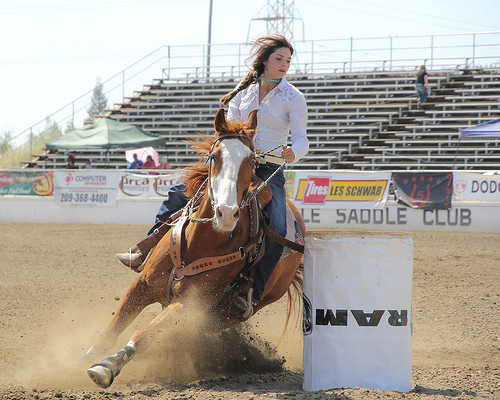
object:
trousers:
[141, 155, 290, 297]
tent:
[450, 115, 498, 171]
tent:
[44, 114, 169, 170]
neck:
[261, 75, 285, 83]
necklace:
[255, 76, 281, 83]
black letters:
[459, 208, 473, 228]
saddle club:
[335, 207, 472, 227]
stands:
[46, 63, 499, 167]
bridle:
[164, 210, 264, 293]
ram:
[315, 309, 408, 327]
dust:
[9, 272, 284, 389]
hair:
[224, 36, 292, 103]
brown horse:
[78, 105, 308, 386]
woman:
[117, 31, 312, 306]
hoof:
[84, 362, 115, 393]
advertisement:
[292, 170, 392, 209]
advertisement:
[389, 172, 451, 207]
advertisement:
[452, 169, 498, 199]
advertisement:
[116, 171, 187, 198]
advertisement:
[52, 167, 119, 206]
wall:
[1, 169, 498, 233]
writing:
[313, 307, 409, 328]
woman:
[414, 65, 429, 110]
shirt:
[227, 79, 308, 167]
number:
[59, 192, 109, 203]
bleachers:
[27, 69, 497, 174]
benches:
[405, 124, 499, 132]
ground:
[1, 206, 496, 398]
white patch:
[217, 136, 247, 215]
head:
[202, 102, 258, 235]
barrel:
[300, 239, 411, 397]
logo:
[300, 296, 409, 335]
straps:
[90, 347, 134, 387]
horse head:
[202, 107, 261, 236]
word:
[316, 309, 347, 326]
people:
[141, 155, 156, 170]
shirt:
[417, 70, 429, 84]